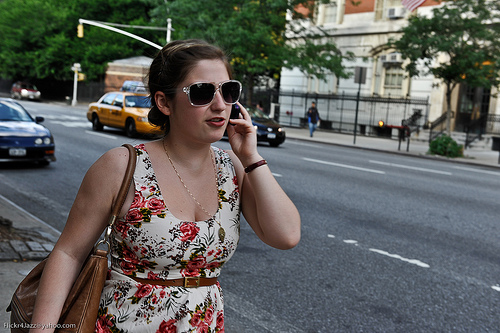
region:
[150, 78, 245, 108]
Very dark modern sunglasses.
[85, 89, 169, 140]
Taxi cab on city street.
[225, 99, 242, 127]
Cell phone being used for voice.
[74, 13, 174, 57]
Over hanging street lamp and support.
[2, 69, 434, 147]
Traditional iron fence for urban area.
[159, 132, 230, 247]
Gold necklace with pendant and cleavage.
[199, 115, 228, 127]
Human lips twisted out of shape by scorn.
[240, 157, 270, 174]
Leather watch wristband on wrist.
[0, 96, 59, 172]
Older Lexus automobile driving on street.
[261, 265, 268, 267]
motorcycle in a field with gravel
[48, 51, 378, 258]
this is a woman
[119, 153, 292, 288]
the woman has on a dress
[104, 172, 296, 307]
the dress is floral pattern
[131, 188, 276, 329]
the dress has roses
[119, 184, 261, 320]
the dress is red and white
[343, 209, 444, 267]
the lines are fading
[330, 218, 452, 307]
the lines are white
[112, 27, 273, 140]
the girl has sunglasses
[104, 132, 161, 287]
the girl has a large purse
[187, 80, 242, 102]
Sunglasses on woman's face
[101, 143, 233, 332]
Flower print dress on a woman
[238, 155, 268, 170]
Brown watchband on woman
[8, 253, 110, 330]
Brown purse under woman's arm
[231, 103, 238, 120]
Cell phone in woman's hand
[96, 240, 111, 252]
Metal loop on a purse strap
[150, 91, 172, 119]
Ear on a woman's head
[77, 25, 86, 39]
Traffic light hanging from a pole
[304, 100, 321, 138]
Man walking on a sidewalk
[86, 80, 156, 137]
Yellow cab on the street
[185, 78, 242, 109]
Sunglasses on girl's face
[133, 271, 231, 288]
Brown belt around girl's waist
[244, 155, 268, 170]
Brown watchband on girl's wrist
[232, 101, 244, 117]
Black cell phone in girl's hand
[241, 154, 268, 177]
watch on a woman's wrist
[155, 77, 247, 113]
sunglasses being worn by a woman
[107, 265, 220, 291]
brown belt on a dress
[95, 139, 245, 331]
white dress with red flowers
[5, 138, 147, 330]
brown purse hanging on a woman's shoulder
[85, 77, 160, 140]
yellow taxi cab on the street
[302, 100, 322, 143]
a person with blue pants walking on the sidewalk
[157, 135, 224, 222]
a necklace around a woman's neck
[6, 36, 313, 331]
a woman talking on a cellphone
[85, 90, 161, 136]
yellow taxi in middle of street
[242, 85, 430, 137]
black fence in front of building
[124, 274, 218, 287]
thin brown belt with buckle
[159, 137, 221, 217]
long gold chain around neck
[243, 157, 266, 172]
watchband around wrist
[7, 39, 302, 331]
woman talking on cell phone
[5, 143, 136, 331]
brown leather purse under arm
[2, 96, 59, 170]
car is parked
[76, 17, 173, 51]
traffic signal attached to long arm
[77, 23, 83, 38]
traffic signal suspended above street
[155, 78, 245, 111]
clear framed sunglasses on woman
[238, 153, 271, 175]
brown leather watch on wrist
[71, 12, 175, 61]
street light over street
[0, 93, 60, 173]
black car on street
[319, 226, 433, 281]
white line painted on street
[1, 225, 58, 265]
bricks on ground of sidewalk